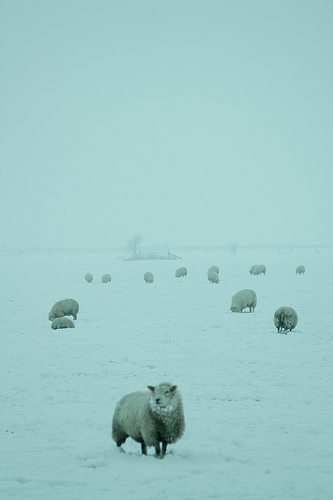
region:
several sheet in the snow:
[38, 228, 325, 465]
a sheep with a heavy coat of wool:
[105, 380, 192, 463]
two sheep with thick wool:
[40, 297, 80, 334]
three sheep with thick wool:
[43, 293, 197, 464]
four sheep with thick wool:
[47, 287, 300, 351]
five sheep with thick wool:
[40, 285, 302, 458]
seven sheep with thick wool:
[203, 260, 311, 335]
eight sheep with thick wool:
[77, 258, 275, 287]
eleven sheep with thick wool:
[81, 257, 318, 339]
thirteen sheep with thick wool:
[40, 261, 331, 348]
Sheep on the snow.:
[107, 379, 185, 460]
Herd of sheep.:
[46, 261, 313, 454]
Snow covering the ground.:
[0, 249, 332, 498]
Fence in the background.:
[121, 249, 180, 263]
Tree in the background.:
[122, 233, 143, 258]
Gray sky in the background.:
[0, 3, 330, 244]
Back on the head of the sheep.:
[273, 310, 290, 326]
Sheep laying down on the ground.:
[47, 317, 80, 333]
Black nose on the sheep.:
[152, 395, 161, 406]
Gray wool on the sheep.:
[229, 287, 260, 314]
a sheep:
[107, 386, 193, 466]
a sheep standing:
[116, 383, 184, 458]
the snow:
[210, 400, 317, 486]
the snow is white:
[204, 380, 303, 485]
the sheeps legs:
[149, 444, 170, 456]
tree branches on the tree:
[125, 234, 146, 254]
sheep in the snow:
[291, 260, 310, 277]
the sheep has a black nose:
[154, 398, 162, 403]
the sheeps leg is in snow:
[108, 441, 122, 450]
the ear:
[169, 383, 178, 392]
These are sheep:
[74, 319, 182, 487]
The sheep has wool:
[105, 392, 219, 448]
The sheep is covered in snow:
[137, 397, 210, 441]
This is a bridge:
[110, 239, 187, 285]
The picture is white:
[82, 231, 248, 386]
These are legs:
[136, 446, 201, 451]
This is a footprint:
[208, 414, 246, 492]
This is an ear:
[136, 381, 165, 395]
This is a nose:
[151, 396, 173, 408]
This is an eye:
[145, 388, 190, 411]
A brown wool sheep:
[118, 379, 203, 450]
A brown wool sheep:
[271, 295, 295, 349]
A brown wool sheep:
[233, 286, 257, 316]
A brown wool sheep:
[48, 313, 71, 330]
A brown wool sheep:
[43, 298, 79, 317]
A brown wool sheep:
[99, 270, 112, 285]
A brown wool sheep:
[83, 267, 92, 284]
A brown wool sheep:
[143, 271, 158, 284]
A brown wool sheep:
[175, 262, 188, 282]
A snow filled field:
[211, 347, 285, 428]